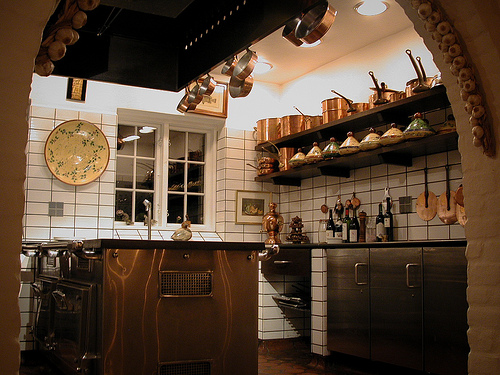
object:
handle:
[403, 262, 417, 292]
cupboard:
[367, 246, 424, 374]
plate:
[42, 118, 111, 188]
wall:
[19, 70, 296, 357]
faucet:
[143, 197, 156, 243]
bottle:
[381, 196, 394, 243]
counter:
[278, 236, 474, 250]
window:
[113, 107, 220, 234]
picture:
[235, 188, 272, 224]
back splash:
[273, 149, 465, 242]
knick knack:
[170, 222, 193, 241]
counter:
[22, 238, 268, 250]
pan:
[293, 2, 337, 47]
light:
[353, 1, 391, 20]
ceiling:
[207, 0, 413, 91]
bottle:
[371, 201, 385, 242]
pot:
[253, 117, 282, 143]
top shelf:
[252, 85, 451, 155]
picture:
[183, 77, 231, 121]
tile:
[74, 191, 99, 207]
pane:
[133, 157, 156, 192]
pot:
[278, 112, 313, 139]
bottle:
[346, 199, 361, 244]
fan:
[413, 159, 439, 222]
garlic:
[34, 57, 58, 77]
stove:
[20, 238, 267, 374]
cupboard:
[324, 247, 373, 365]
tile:
[225, 167, 244, 181]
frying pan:
[403, 74, 433, 99]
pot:
[301, 114, 322, 130]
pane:
[164, 159, 188, 193]